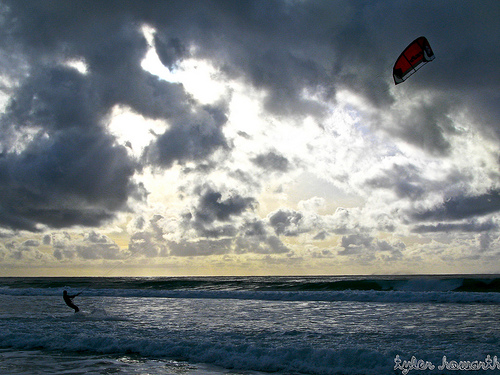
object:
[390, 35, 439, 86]
kite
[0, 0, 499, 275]
sky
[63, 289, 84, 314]
man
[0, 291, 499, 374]
water